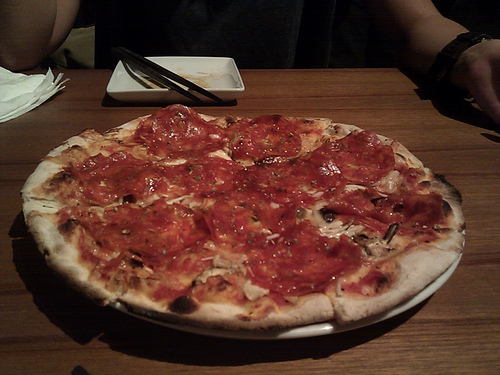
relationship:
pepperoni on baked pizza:
[66, 104, 447, 292] [43, 104, 467, 328]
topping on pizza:
[285, 201, 365, 288] [322, 164, 427, 228]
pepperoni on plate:
[133, 106, 220, 158] [14, 95, 480, 350]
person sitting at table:
[1, 0, 498, 121] [2, 68, 495, 373]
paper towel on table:
[3, 62, 84, 132] [239, 46, 414, 121]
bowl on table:
[110, 53, 249, 105] [2, 68, 495, 373]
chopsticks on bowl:
[108, 40, 228, 106] [106, 47, 251, 106]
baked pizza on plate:
[43, 104, 467, 328] [108, 224, 465, 340]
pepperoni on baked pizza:
[240, 117, 300, 157] [43, 104, 467, 328]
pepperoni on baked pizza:
[336, 145, 398, 185] [43, 104, 467, 328]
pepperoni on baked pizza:
[133, 106, 220, 158] [43, 104, 467, 328]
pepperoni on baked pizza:
[328, 127, 380, 157] [43, 104, 467, 328]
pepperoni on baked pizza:
[121, 199, 214, 260] [43, 104, 467, 328]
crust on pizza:
[323, 238, 472, 320] [27, 82, 479, 363]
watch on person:
[414, 31, 483, 98] [371, 0, 498, 119]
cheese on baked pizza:
[96, 120, 373, 282] [43, 104, 467, 328]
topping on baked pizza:
[200, 192, 285, 254] [43, 104, 467, 328]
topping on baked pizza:
[148, 261, 171, 282] [43, 104, 467, 328]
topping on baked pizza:
[203, 207, 250, 237] [43, 104, 467, 328]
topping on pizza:
[243, 185, 329, 251] [31, 110, 468, 335]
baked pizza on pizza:
[43, 104, 467, 328] [79, 123, 388, 305]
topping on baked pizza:
[266, 155, 326, 203] [43, 104, 467, 328]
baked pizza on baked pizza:
[43, 104, 467, 328] [43, 104, 467, 328]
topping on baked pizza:
[248, 166, 306, 213] [43, 104, 467, 328]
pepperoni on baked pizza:
[248, 222, 359, 291] [43, 99, 408, 341]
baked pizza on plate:
[43, 99, 408, 341] [102, 176, 466, 338]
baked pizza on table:
[43, 104, 467, 328] [2, 68, 495, 373]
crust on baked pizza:
[145, 288, 366, 330] [43, 104, 467, 328]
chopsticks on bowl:
[108, 40, 228, 106] [110, 53, 249, 105]